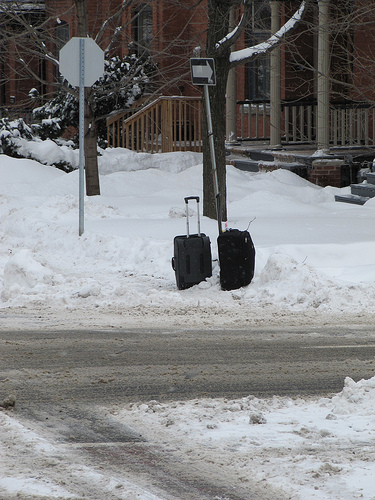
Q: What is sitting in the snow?
A: Suitcases.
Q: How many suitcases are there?
A: Two.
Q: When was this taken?
A: During the day.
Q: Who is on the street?
A: No one.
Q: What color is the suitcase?
A: Black.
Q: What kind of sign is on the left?
A: Stop sign.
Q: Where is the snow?
A: On the ground.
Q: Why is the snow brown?
A: Dirt.